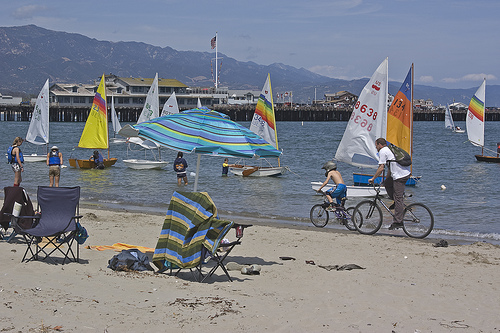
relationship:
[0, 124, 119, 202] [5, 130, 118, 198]
vest on people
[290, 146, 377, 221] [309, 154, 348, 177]
boy wearing helmet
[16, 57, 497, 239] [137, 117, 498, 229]
sailboats in water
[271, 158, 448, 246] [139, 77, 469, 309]
bikes along beach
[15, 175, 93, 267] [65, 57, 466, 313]
chair on beach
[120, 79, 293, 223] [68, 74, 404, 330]
umbrella on beach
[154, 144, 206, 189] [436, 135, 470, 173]
girl in water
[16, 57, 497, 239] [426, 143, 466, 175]
sailboats in water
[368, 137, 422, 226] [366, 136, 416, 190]
person wears t-shirt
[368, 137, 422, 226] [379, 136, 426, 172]
person carries a backpack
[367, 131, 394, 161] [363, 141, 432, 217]
head of a man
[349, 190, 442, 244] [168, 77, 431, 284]
bicycle on beach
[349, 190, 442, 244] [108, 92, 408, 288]
bicycle along beach